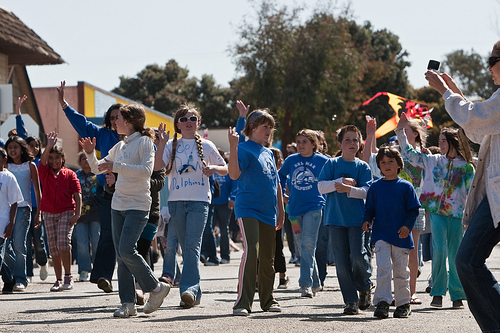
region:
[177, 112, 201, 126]
sunglasses on a girl's face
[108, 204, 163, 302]
blue jeans on a girl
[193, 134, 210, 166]
a braid in a girl's hair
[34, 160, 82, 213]
a red shirt on a girl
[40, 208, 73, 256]
plaid pants on a girl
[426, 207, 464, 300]
blue pants on a girl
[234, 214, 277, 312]
brown pants with pink stripe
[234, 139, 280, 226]
a blue shirt on a girl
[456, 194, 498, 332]
blue jeans on a woman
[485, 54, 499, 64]
sunglasses on a woman's face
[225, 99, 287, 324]
This is a person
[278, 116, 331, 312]
This is a person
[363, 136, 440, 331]
This is a person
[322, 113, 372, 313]
This is a person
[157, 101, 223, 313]
This is a person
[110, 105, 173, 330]
This is a person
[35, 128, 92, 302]
This is a person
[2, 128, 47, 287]
This is a person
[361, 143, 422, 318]
child walking in parade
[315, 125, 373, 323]
child walking in parade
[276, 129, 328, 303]
child walking in parade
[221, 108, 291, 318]
child walking in parade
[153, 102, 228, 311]
child walking in parade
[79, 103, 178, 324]
child walking in parade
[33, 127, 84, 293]
child walking in parade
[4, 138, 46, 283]
child walking in parade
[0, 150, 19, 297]
child walking in parade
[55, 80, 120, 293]
child walking in parade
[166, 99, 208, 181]
The girl has brown hair.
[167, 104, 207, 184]
The girl has pigtails.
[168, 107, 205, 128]
The girl is wearing sun glasses.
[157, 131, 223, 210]
The girl is wearing a white shirt.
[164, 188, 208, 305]
The girl is wearing blue pants.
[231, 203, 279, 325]
The boy is wearing brown pants.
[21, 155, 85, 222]
The girl is wearing a red shirt.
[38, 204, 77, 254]
The girl is wearing plaid pants.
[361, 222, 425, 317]
The boy is wearing white pants.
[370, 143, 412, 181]
The boy has dark hair.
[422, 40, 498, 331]
a woman taking a picture of a group of children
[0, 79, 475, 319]
children participating in a parade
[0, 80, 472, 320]
young boys and girls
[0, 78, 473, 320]
children walking in the street waving to spectators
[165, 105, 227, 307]
a teenage girl wearing sunglasses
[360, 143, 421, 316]
a young boy in a blue t-shirt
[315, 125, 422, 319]
two young boys walking in a parade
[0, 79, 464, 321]
children and an adult waving to the spectators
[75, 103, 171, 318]
a teenager in a white shirt